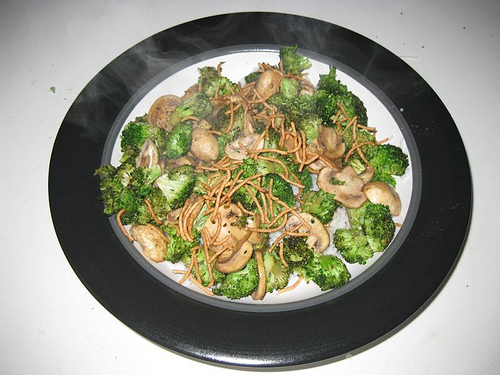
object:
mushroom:
[218, 94, 248, 112]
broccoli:
[120, 122, 159, 156]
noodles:
[181, 244, 223, 290]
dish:
[46, 11, 472, 367]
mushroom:
[188, 120, 219, 163]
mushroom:
[242, 111, 254, 136]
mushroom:
[309, 158, 328, 170]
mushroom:
[189, 128, 219, 162]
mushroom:
[298, 81, 315, 97]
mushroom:
[166, 156, 193, 173]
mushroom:
[285, 212, 330, 253]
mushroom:
[166, 207, 183, 225]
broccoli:
[363, 203, 396, 252]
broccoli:
[302, 254, 352, 290]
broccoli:
[367, 145, 408, 176]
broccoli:
[90, 163, 162, 216]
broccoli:
[276, 46, 312, 72]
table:
[0, 0, 500, 374]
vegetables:
[333, 203, 396, 265]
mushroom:
[213, 230, 253, 273]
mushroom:
[254, 69, 281, 99]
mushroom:
[317, 167, 374, 209]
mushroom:
[224, 133, 264, 161]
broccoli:
[300, 190, 336, 225]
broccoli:
[155, 164, 197, 210]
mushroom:
[283, 136, 303, 161]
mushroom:
[148, 94, 183, 133]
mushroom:
[129, 222, 165, 263]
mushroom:
[250, 251, 266, 301]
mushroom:
[203, 202, 251, 263]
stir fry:
[92, 44, 408, 300]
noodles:
[179, 196, 207, 242]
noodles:
[212, 93, 322, 165]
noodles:
[204, 170, 301, 202]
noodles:
[116, 208, 134, 241]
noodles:
[270, 223, 308, 267]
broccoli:
[242, 158, 275, 180]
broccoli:
[333, 228, 374, 265]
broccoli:
[212, 258, 258, 300]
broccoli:
[175, 91, 213, 118]